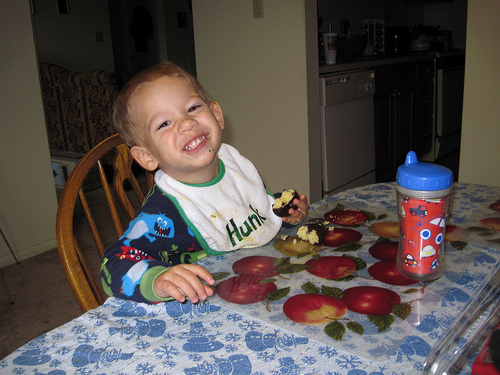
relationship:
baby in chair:
[97, 60, 309, 306] [55, 131, 154, 308]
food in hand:
[270, 185, 306, 218] [276, 189, 313, 223]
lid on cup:
[393, 145, 454, 190] [393, 149, 455, 281]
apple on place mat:
[339, 284, 401, 316] [187, 201, 468, 367]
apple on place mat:
[212, 270, 289, 307] [187, 201, 468, 367]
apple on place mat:
[230, 253, 303, 277] [187, 201, 468, 367]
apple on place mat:
[304, 253, 356, 280] [187, 201, 468, 367]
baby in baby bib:
[97, 60, 309, 306] [153, 144, 286, 256]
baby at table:
[97, 60, 309, 306] [0, 180, 500, 371]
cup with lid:
[399, 185, 448, 277] [393, 149, 453, 192]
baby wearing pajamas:
[99, 58, 309, 305] [99, 172, 208, 318]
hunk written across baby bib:
[224, 204, 270, 245] [153, 144, 286, 256]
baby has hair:
[97, 60, 309, 306] [111, 56, 211, 145]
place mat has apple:
[195, 200, 489, 358] [288, 287, 400, 322]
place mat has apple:
[195, 200, 489, 358] [305, 252, 361, 280]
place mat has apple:
[195, 200, 489, 358] [319, 207, 368, 250]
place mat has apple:
[195, 200, 489, 358] [222, 250, 283, 301]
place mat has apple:
[195, 200, 489, 358] [370, 233, 416, 283]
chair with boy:
[57, 133, 157, 323] [113, 61, 308, 302]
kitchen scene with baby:
[2, 1, 499, 371] [99, 58, 309, 305]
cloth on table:
[1, 176, 499, 365] [0, 180, 500, 371]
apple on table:
[280, 290, 347, 325] [0, 180, 500, 371]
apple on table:
[339, 284, 401, 316] [0, 180, 500, 371]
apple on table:
[367, 258, 446, 294] [0, 180, 500, 371]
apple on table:
[211, 272, 275, 304] [0, 180, 500, 371]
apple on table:
[304, 253, 367, 281] [0, 180, 500, 371]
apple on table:
[230, 253, 276, 279] [0, 180, 500, 371]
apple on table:
[309, 226, 366, 251] [0, 180, 500, 371]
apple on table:
[320, 205, 376, 229] [0, 180, 500, 371]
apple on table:
[372, 217, 402, 242] [0, 180, 500, 371]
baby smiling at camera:
[97, 60, 309, 306] [2, 2, 495, 372]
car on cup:
[414, 213, 445, 243] [395, 149, 455, 282]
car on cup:
[404, 254, 420, 264] [395, 149, 455, 282]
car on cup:
[404, 201, 428, 216] [395, 149, 455, 282]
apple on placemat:
[279, 290, 366, 340] [210, 201, 470, 360]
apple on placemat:
[341, 282, 414, 327] [210, 201, 470, 360]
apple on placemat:
[211, 272, 275, 304] [210, 201, 470, 360]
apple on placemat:
[304, 253, 367, 281] [210, 201, 470, 360]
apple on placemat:
[367, 258, 416, 287] [210, 201, 470, 360]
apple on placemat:
[230, 253, 276, 279] [210, 201, 470, 360]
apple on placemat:
[368, 235, 401, 260] [210, 201, 470, 360]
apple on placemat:
[320, 205, 376, 229] [210, 201, 470, 360]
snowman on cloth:
[71, 343, 137, 365] [1, 182, 499, 373]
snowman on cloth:
[180, 319, 224, 350] [1, 182, 499, 373]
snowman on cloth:
[244, 328, 310, 352] [1, 182, 499, 373]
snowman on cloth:
[181, 352, 253, 375] [1, 182, 499, 373]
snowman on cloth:
[110, 315, 166, 336] [1, 182, 499, 373]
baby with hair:
[97, 60, 309, 306] [111, 56, 211, 145]